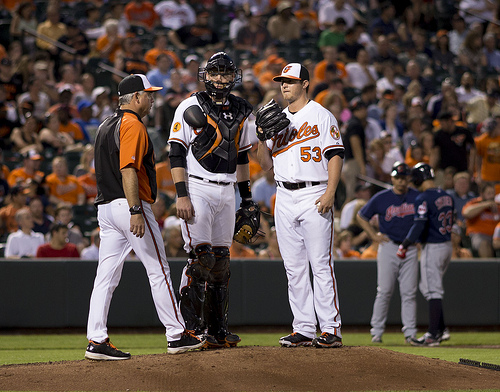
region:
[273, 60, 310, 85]
an orange, black and white baseball cap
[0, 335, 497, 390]
a pitcher's mound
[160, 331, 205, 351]
a man's tennis shoe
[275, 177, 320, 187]
a man's black belt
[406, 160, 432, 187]
a black helmet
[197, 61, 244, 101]
a black face mask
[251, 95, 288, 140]
a black baseball glove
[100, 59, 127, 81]
a long black pole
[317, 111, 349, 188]
the arm of a man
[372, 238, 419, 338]
a man's gray uniform pants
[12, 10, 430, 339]
baseball players on field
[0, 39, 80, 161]
fans in the stands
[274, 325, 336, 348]
the shoes are black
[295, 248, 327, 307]
the pants are white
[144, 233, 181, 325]
stripe on the pants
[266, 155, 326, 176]
the shirt is white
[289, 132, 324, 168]
53 on the shirt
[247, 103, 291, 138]
mitt on the hand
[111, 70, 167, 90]
hat on the head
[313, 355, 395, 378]
mound on the field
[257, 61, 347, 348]
a pitcher standing on a pitcher's mound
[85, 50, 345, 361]
three men standing on a pitcher's mound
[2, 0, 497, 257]
people watching a baseball game from the bleachers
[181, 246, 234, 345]
catcher wearing knee protection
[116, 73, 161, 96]
man wearing a black, white and orange cap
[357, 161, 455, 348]
two baseball player wearing blue and gray uniforms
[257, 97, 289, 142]
a black leather catcher's mitt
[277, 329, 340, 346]
man wearing black shoes with orange shoelaces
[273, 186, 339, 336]
man wearing white pants with a red line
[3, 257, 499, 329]
a green fence between the baseball field and the bleachers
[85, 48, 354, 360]
Players talking to a coach.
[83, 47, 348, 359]
Two baseball players talking to a coach.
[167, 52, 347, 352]
The pitcher and the catcher for the Orioles.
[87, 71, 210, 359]
An Orioles coach walking on the pitchers mound.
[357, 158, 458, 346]
Two players talking to one another.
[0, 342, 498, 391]
The pitcher's mound.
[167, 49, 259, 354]
Catcher in protective gear.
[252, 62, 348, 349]
Orioles pitcher, number 53.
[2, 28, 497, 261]
Crowd of spectators, many in orange.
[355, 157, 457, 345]
Number 33 talking with a fellow player.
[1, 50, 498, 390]
two professional baseball teams on the field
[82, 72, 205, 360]
the Orioles baseball coach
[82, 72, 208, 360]
an Orioles coach speaking to two baseball players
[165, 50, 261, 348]
an Orioles baseball catcher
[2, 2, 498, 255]
spectators watching a professional baseball game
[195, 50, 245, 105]
a black face and head gear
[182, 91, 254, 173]
protective gear for the chest